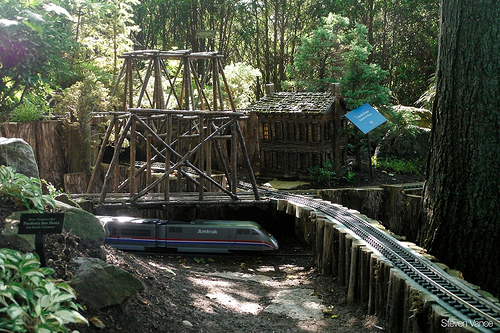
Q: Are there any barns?
A: No, there are no barns.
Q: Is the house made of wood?
A: Yes, the house is made of wood.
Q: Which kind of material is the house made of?
A: The house is made of wood.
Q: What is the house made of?
A: The house is made of wood.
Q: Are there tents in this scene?
A: No, there are no tents.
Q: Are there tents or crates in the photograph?
A: No, there are no tents or crates.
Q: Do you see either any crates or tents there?
A: No, there are no tents or crates.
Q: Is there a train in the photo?
A: Yes, there is a train.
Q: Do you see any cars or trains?
A: Yes, there is a train.